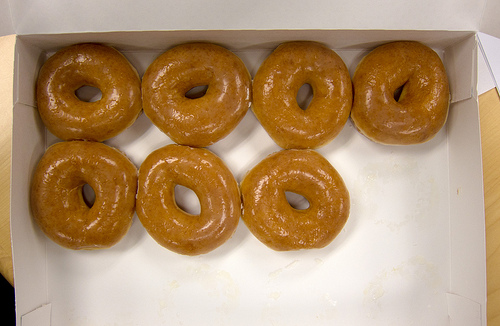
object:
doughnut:
[35, 41, 142, 142]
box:
[10, 29, 489, 325]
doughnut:
[139, 42, 250, 147]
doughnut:
[31, 139, 139, 250]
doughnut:
[135, 144, 241, 256]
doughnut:
[250, 40, 357, 151]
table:
[0, 33, 500, 326]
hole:
[74, 85, 103, 102]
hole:
[185, 84, 209, 99]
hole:
[296, 83, 314, 111]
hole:
[82, 182, 97, 209]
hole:
[174, 184, 202, 215]